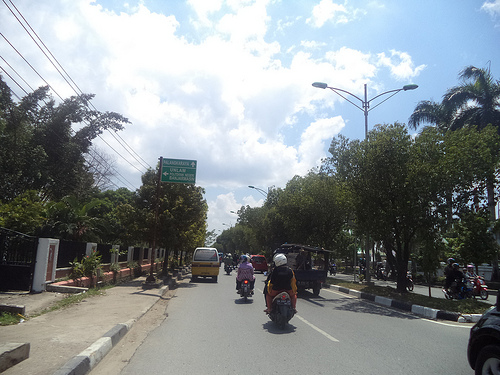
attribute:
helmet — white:
[272, 254, 288, 268]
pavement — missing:
[82, 282, 176, 374]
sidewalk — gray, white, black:
[326, 276, 493, 322]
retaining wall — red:
[34, 239, 185, 296]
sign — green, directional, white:
[160, 157, 196, 184]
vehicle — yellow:
[190, 248, 222, 281]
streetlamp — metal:
[313, 82, 419, 283]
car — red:
[251, 254, 268, 274]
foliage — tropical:
[407, 63, 499, 132]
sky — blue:
[3, 1, 500, 247]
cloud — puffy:
[382, 50, 424, 82]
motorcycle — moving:
[263, 276, 295, 330]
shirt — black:
[446, 268, 463, 284]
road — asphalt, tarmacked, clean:
[88, 260, 475, 374]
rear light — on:
[244, 279, 250, 285]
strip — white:
[293, 311, 339, 344]